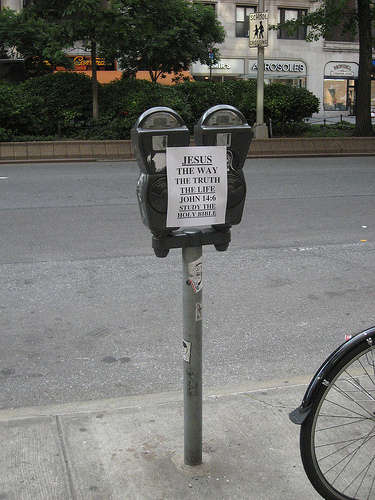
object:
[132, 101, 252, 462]
parking meter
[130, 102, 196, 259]
parking meter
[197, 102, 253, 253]
parking meter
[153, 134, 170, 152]
coin slot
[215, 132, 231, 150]
coin slot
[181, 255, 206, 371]
stickers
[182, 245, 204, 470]
pole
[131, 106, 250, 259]
meters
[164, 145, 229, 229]
sign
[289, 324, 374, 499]
bicycle wheel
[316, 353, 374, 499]
spokes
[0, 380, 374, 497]
sidewalk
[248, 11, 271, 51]
cossing sign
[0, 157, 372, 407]
street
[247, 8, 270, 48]
sign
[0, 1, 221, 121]
tree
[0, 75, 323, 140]
bushes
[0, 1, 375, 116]
store fronts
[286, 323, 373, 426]
metal fender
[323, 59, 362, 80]
motel sign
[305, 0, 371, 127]
motel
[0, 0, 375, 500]
concrete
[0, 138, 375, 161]
concrete barrier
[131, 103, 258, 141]
top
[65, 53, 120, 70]
business name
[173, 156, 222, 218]
writing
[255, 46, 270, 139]
metal pole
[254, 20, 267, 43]
drawing